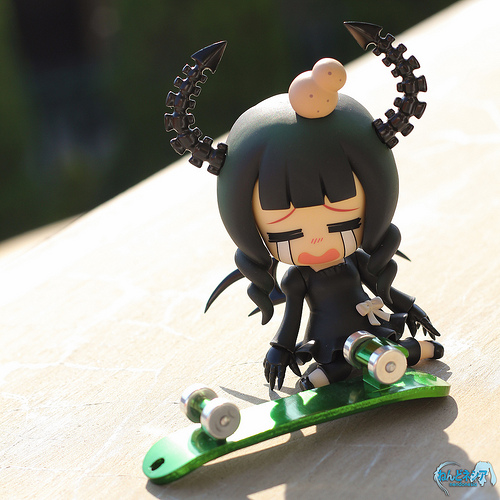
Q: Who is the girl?
A: A character.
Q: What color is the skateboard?
A: Green.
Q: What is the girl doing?
A: Crying.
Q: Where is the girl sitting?
A: Next to the skateboard.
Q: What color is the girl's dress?
A: Black.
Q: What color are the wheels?
A: Silver.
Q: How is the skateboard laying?
A: Upside down.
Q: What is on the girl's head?
A: Horns.